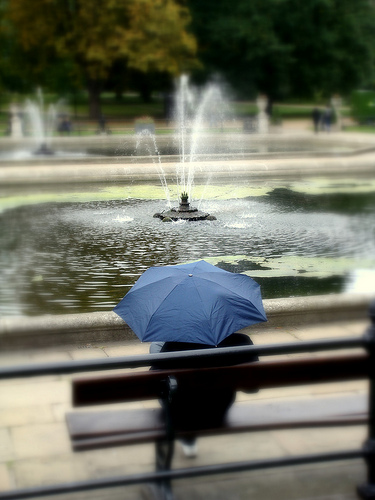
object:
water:
[149, 64, 249, 192]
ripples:
[8, 172, 373, 331]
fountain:
[3, 148, 289, 284]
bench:
[30, 313, 368, 484]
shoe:
[178, 438, 201, 458]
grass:
[3, 88, 374, 131]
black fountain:
[157, 187, 213, 219]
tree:
[8, 7, 207, 107]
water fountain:
[0, 53, 292, 235]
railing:
[1, 335, 374, 498]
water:
[41, 214, 343, 263]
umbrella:
[110, 260, 266, 346]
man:
[147, 332, 259, 457]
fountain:
[152, 191, 217, 221]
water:
[0, 71, 373, 315]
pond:
[7, 199, 373, 293]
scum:
[102, 181, 255, 200]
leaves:
[99, 34, 152, 81]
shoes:
[173, 437, 201, 458]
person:
[147, 332, 258, 457]